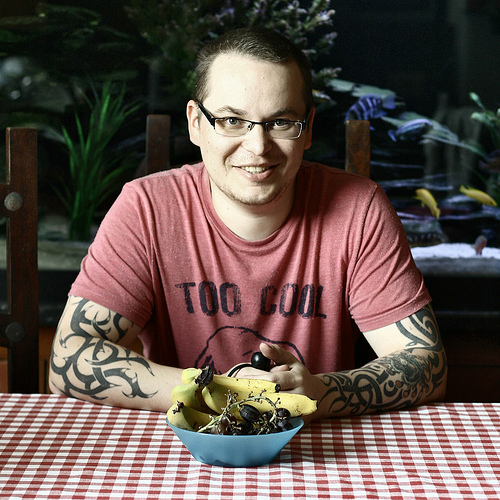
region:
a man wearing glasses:
[181, 52, 329, 204]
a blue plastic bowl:
[157, 422, 333, 468]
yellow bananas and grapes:
[168, 361, 310, 443]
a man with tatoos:
[41, 71, 453, 430]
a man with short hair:
[173, 31, 330, 172]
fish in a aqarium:
[336, 72, 493, 234]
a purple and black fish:
[335, 90, 398, 140]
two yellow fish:
[391, 180, 496, 230]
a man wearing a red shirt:
[121, 82, 379, 292]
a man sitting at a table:
[63, 62, 375, 485]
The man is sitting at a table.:
[40, 18, 450, 473]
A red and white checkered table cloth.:
[0, 390, 496, 498]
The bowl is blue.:
[162, 410, 312, 470]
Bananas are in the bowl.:
[168, 355, 318, 425]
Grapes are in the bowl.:
[203, 390, 293, 435]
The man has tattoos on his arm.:
[45, 273, 166, 413]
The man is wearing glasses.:
[188, 85, 315, 141]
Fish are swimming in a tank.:
[316, 50, 493, 225]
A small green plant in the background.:
[31, 67, 141, 249]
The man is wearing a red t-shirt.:
[65, 162, 439, 379]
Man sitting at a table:
[69, 25, 441, 450]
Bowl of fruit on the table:
[165, 357, 326, 480]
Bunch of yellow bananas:
[170, 343, 290, 429]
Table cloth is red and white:
[36, 394, 132, 496]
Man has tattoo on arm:
[314, 343, 494, 432]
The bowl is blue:
[162, 408, 324, 490]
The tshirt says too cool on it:
[156, 266, 353, 356]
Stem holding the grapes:
[210, 391, 266, 441]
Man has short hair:
[165, 32, 349, 137]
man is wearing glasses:
[167, 95, 347, 187]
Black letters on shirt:
[167, 265, 335, 327]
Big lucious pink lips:
[225, 151, 289, 182]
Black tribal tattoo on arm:
[37, 289, 157, 402]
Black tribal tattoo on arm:
[313, 315, 483, 421]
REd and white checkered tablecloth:
[339, 443, 467, 495]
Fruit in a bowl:
[151, 353, 332, 478]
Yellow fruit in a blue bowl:
[157, 355, 322, 425]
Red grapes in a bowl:
[200, 397, 291, 437]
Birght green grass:
[55, 84, 116, 201]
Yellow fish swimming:
[404, 151, 497, 256]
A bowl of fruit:
[164, 368, 308, 467]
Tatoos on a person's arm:
[331, 330, 454, 407]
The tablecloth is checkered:
[22, 414, 149, 496]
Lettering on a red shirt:
[177, 267, 336, 330]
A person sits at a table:
[51, 41, 450, 409]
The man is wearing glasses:
[185, 33, 312, 205]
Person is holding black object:
[230, 343, 315, 382]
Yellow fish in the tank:
[409, 183, 444, 220]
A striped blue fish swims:
[346, 89, 386, 124]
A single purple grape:
[238, 399, 256, 421]